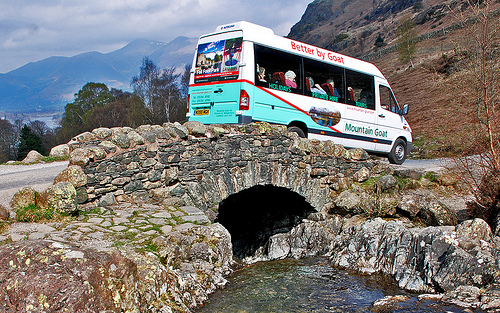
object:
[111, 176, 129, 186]
rock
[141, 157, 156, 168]
rock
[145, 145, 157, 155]
rock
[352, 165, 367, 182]
rock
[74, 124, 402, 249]
bridge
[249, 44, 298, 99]
window van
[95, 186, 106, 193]
rock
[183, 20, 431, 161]
passenger van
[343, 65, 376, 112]
window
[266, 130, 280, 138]
rocks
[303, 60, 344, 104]
window